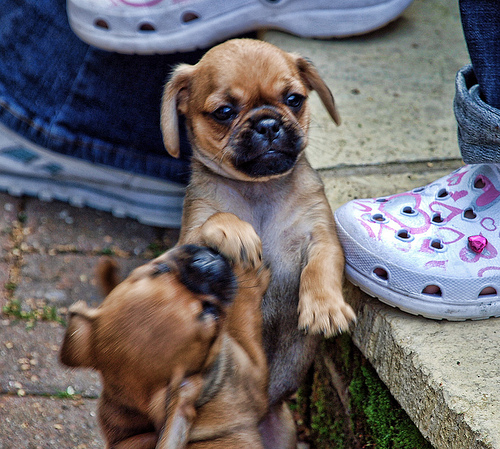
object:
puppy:
[61, 243, 271, 448]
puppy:
[159, 38, 358, 449]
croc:
[334, 164, 499, 321]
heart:
[378, 192, 431, 233]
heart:
[468, 234, 487, 252]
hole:
[421, 284, 441, 296]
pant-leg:
[453, 1, 499, 166]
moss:
[335, 394, 405, 448]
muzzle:
[234, 121, 298, 176]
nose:
[258, 119, 278, 136]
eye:
[286, 94, 303, 108]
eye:
[213, 106, 233, 118]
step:
[260, 3, 499, 448]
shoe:
[67, 1, 416, 55]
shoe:
[1, 124, 185, 229]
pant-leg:
[0, 1, 207, 183]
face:
[143, 245, 238, 323]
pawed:
[201, 212, 263, 267]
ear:
[159, 63, 191, 157]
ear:
[295, 53, 341, 126]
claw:
[233, 259, 271, 298]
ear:
[59, 300, 103, 369]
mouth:
[235, 146, 297, 165]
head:
[62, 245, 234, 449]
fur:
[59, 258, 272, 449]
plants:
[5, 298, 61, 326]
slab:
[326, 289, 499, 447]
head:
[160, 36, 342, 181]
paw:
[296, 279, 358, 339]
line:
[1, 389, 98, 400]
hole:
[182, 11, 197, 23]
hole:
[139, 22, 155, 31]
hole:
[95, 17, 107, 29]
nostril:
[260, 126, 267, 136]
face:
[204, 81, 309, 168]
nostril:
[272, 124, 279, 134]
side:
[289, 332, 437, 449]